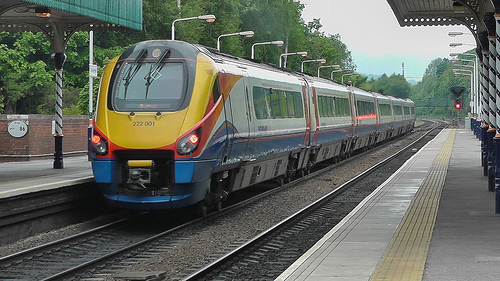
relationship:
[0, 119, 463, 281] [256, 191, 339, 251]
railway has ballast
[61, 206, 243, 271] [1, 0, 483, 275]
railway in photo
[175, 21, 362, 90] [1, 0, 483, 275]
lights in photo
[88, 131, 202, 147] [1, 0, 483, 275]
headlights in photo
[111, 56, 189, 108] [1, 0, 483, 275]
windscreen in photo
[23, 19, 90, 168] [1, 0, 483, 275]
pole in photo